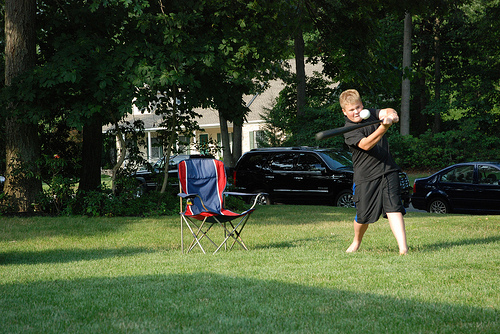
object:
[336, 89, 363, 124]
head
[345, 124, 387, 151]
arm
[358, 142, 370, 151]
elbow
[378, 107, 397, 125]
hand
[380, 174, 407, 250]
leg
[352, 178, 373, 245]
leg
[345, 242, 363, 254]
foot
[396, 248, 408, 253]
foot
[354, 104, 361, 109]
eye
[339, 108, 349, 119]
ear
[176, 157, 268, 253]
chair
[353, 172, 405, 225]
shorts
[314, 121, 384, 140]
bat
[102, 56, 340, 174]
house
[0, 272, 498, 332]
shadow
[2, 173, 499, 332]
grass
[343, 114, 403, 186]
black shirt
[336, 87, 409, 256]
boy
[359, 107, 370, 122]
ball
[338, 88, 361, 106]
hair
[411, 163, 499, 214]
car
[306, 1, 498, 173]
trees